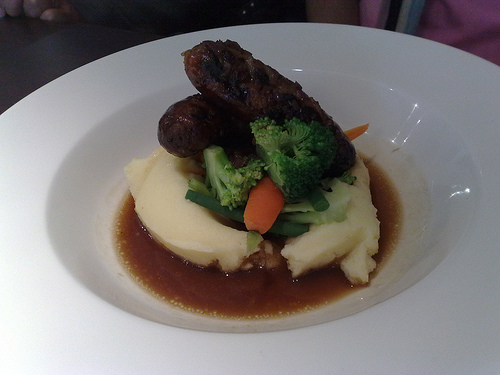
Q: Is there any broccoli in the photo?
A: Yes, there is broccoli.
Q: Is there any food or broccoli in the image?
A: Yes, there is broccoli.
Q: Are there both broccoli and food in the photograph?
A: Yes, there are both broccoli and food.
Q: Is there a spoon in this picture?
A: No, there are no spoons.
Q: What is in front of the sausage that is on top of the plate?
A: The broccoli is in front of the sausage.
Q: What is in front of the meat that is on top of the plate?
A: The broccoli is in front of the sausage.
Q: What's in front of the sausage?
A: The broccoli is in front of the sausage.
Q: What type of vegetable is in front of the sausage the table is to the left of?
A: The vegetable is broccoli.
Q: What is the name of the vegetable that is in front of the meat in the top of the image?
A: The vegetable is broccoli.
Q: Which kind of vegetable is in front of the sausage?
A: The vegetable is broccoli.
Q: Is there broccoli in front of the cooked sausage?
A: Yes, there is broccoli in front of the sausage.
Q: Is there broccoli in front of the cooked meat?
A: Yes, there is broccoli in front of the sausage.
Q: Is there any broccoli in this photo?
A: Yes, there is broccoli.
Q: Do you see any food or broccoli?
A: Yes, there is broccoli.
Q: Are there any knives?
A: No, there are no knives.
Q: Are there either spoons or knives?
A: No, there are no knives or spoons.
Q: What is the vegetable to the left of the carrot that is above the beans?
A: The vegetable is broccoli.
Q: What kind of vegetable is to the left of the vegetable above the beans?
A: The vegetable is broccoli.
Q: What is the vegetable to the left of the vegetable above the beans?
A: The vegetable is broccoli.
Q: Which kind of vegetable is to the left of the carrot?
A: The vegetable is broccoli.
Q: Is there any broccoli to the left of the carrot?
A: Yes, there is broccoli to the left of the carrot.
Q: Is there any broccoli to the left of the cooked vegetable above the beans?
A: Yes, there is broccoli to the left of the carrot.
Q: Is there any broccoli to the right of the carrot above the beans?
A: No, the broccoli is to the left of the carrot.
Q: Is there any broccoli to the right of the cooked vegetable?
A: No, the broccoli is to the left of the carrot.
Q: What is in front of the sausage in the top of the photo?
A: The broccoli is in front of the sausage.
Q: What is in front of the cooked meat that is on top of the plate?
A: The broccoli is in front of the sausage.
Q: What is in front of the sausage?
A: The broccoli is in front of the sausage.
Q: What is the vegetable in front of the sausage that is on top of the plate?
A: The vegetable is broccoli.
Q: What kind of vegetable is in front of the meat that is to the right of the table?
A: The vegetable is broccoli.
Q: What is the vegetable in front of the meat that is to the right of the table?
A: The vegetable is broccoli.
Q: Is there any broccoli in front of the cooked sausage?
A: Yes, there is broccoli in front of the sausage.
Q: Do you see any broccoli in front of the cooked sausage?
A: Yes, there is broccoli in front of the sausage.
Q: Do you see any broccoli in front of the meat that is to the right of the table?
A: Yes, there is broccoli in front of the sausage.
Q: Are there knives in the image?
A: No, there are no knives.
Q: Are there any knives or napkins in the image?
A: No, there are no knives or napkins.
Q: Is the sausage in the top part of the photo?
A: Yes, the sausage is in the top of the image.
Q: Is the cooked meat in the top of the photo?
A: Yes, the sausage is in the top of the image.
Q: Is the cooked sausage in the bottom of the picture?
A: No, the sausage is in the top of the image.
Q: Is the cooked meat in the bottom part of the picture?
A: No, the sausage is in the top of the image.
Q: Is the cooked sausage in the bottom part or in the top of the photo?
A: The sausage is in the top of the image.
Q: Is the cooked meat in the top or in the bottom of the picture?
A: The sausage is in the top of the image.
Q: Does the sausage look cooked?
A: Yes, the sausage is cooked.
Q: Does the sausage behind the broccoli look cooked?
A: Yes, the sausage is cooked.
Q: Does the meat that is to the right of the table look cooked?
A: Yes, the sausage is cooked.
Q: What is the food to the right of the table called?
A: The food is a sausage.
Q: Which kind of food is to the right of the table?
A: The food is a sausage.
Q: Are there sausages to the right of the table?
A: Yes, there is a sausage to the right of the table.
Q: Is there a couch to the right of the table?
A: No, there is a sausage to the right of the table.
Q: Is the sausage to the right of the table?
A: Yes, the sausage is to the right of the table.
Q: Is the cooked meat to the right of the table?
A: Yes, the sausage is to the right of the table.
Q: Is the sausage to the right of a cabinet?
A: No, the sausage is to the right of the table.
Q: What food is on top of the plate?
A: The food is a sausage.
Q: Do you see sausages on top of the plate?
A: Yes, there is a sausage on top of the plate.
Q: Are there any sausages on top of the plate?
A: Yes, there is a sausage on top of the plate.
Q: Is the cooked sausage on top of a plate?
A: Yes, the sausage is on top of a plate.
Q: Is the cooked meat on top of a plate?
A: Yes, the sausage is on top of a plate.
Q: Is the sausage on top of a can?
A: No, the sausage is on top of a plate.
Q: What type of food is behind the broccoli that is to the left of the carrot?
A: The food is a sausage.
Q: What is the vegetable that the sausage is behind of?
A: The vegetable is broccoli.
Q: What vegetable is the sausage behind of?
A: The sausage is behind the broccoli.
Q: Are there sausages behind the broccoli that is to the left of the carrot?
A: Yes, there is a sausage behind the broccoli.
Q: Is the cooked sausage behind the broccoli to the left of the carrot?
A: Yes, the sausage is behind the broccoli.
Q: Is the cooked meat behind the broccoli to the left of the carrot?
A: Yes, the sausage is behind the broccoli.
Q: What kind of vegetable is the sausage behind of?
A: The sausage is behind the broccoli.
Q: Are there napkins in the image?
A: No, there are no napkins.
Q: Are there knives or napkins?
A: No, there are no napkins or knives.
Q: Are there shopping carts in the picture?
A: No, there are no shopping carts.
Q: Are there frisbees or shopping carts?
A: No, there are no shopping carts or frisbees.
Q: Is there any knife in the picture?
A: No, there are no knives.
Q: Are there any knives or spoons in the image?
A: No, there are no knives or spoons.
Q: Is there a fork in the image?
A: No, there are no forks.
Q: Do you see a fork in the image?
A: No, there are no forks.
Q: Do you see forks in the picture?
A: No, there are no forks.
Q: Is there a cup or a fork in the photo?
A: No, there are no forks or cups.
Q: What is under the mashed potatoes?
A: The gravy is under the mashed potatoes.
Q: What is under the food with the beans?
A: The gravy is under the mashed potatoes.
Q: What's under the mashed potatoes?
A: The gravy is under the mashed potatoes.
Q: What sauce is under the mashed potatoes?
A: The sauce is gravy.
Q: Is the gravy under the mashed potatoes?
A: Yes, the gravy is under the mashed potatoes.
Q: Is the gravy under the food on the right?
A: Yes, the gravy is under the mashed potatoes.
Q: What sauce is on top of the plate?
A: The sauce is gravy.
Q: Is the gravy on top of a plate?
A: Yes, the gravy is on top of a plate.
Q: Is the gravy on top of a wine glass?
A: No, the gravy is on top of a plate.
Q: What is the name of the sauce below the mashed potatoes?
A: The sauce is gravy.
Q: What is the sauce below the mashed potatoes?
A: The sauce is gravy.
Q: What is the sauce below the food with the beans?
A: The sauce is gravy.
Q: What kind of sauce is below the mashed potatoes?
A: The sauce is gravy.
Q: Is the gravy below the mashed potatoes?
A: Yes, the gravy is below the mashed potatoes.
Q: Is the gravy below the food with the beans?
A: Yes, the gravy is below the mashed potatoes.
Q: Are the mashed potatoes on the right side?
A: Yes, the mashed potatoes are on the right of the image.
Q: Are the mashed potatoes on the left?
A: No, the mashed potatoes are on the right of the image.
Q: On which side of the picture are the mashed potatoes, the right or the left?
A: The mashed potatoes are on the right of the image.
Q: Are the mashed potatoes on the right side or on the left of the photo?
A: The mashed potatoes are on the right of the image.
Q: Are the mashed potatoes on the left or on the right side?
A: The mashed potatoes are on the right of the image.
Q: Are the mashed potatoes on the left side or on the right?
A: The mashed potatoes are on the right of the image.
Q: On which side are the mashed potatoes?
A: The mashed potatoes are on the right of the image.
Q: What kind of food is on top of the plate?
A: The food is mashed potatoes.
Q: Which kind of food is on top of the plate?
A: The food is mashed potatoes.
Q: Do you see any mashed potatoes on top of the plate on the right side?
A: Yes, there are mashed potatoes on top of the plate.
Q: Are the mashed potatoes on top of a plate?
A: Yes, the mashed potatoes are on top of a plate.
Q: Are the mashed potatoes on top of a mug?
A: No, the mashed potatoes are on top of a plate.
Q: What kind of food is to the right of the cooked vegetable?
A: The food is mashed potatoes.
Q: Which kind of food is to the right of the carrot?
A: The food is mashed potatoes.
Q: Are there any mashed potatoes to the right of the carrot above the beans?
A: Yes, there are mashed potatoes to the right of the carrot.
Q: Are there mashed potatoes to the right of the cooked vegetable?
A: Yes, there are mashed potatoes to the right of the carrot.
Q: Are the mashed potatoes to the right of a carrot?
A: Yes, the mashed potatoes are to the right of a carrot.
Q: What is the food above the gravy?
A: The food is mashed potatoes.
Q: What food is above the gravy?
A: The food is mashed potatoes.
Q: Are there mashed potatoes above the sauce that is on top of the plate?
A: Yes, there are mashed potatoes above the gravy.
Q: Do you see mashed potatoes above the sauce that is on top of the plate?
A: Yes, there are mashed potatoes above the gravy.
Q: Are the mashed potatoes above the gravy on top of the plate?
A: Yes, the mashed potatoes are above the gravy.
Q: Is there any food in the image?
A: Yes, there is food.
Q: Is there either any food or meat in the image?
A: Yes, there is food.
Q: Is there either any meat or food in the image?
A: Yes, there is food.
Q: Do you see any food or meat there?
A: Yes, there is food.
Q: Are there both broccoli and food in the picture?
A: Yes, there are both food and broccoli.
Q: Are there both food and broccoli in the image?
A: Yes, there are both food and broccoli.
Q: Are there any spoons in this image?
A: No, there are no spoons.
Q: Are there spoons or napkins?
A: No, there are no spoons or napkins.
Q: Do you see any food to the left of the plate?
A: Yes, there is food to the left of the plate.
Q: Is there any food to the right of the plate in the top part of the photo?
A: No, the food is to the left of the plate.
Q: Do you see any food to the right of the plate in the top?
A: No, the food is to the left of the plate.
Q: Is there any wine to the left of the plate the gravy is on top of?
A: No, there is food to the left of the plate.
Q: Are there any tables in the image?
A: Yes, there is a table.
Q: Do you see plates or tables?
A: Yes, there is a table.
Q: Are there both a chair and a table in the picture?
A: No, there is a table but no chairs.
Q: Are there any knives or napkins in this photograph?
A: No, there are no knives or napkins.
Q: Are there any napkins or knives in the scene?
A: No, there are no knives or napkins.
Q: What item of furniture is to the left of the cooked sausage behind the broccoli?
A: The piece of furniture is a table.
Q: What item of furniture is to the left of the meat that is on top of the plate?
A: The piece of furniture is a table.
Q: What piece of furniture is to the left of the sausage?
A: The piece of furniture is a table.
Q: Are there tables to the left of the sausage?
A: Yes, there is a table to the left of the sausage.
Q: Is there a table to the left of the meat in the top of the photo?
A: Yes, there is a table to the left of the sausage.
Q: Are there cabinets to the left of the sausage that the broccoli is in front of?
A: No, there is a table to the left of the sausage.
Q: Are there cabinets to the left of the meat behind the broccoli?
A: No, there is a table to the left of the sausage.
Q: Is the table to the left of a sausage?
A: Yes, the table is to the left of a sausage.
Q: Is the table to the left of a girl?
A: No, the table is to the left of a sausage.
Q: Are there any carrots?
A: Yes, there is a carrot.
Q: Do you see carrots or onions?
A: Yes, there is a carrot.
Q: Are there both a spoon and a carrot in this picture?
A: No, there is a carrot but no spoons.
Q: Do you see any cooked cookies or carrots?
A: Yes, there is a cooked carrot.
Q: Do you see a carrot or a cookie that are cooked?
A: Yes, the carrot is cooked.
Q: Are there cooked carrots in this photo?
A: Yes, there is a cooked carrot.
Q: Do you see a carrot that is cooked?
A: Yes, there is a cooked carrot.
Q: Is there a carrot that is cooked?
A: Yes, there is a carrot that is cooked.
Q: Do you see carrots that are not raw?
A: Yes, there is a cooked carrot.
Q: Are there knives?
A: No, there are no knives.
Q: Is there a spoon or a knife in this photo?
A: No, there are no knives or spoons.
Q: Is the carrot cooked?
A: Yes, the carrot is cooked.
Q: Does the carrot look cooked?
A: Yes, the carrot is cooked.